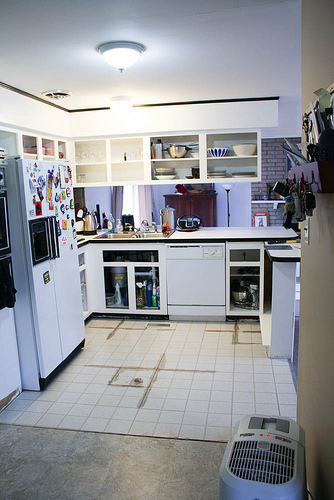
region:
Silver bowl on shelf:
[164, 141, 190, 161]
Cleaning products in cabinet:
[133, 274, 159, 308]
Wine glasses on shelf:
[73, 140, 107, 160]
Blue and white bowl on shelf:
[197, 138, 223, 155]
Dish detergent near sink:
[103, 212, 114, 231]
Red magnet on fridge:
[30, 198, 42, 215]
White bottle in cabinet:
[108, 278, 122, 306]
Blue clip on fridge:
[45, 164, 53, 178]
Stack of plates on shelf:
[151, 164, 176, 179]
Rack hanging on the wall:
[282, 104, 332, 196]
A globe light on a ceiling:
[95, 40, 144, 71]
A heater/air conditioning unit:
[218, 412, 310, 497]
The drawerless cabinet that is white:
[104, 264, 128, 308]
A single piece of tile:
[184, 397, 207, 411]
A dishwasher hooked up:
[165, 243, 224, 317]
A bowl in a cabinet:
[231, 142, 255, 154]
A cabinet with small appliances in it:
[148, 135, 201, 157]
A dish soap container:
[114, 283, 122, 303]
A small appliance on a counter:
[175, 212, 201, 230]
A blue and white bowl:
[207, 146, 228, 155]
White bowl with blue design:
[205, 142, 227, 160]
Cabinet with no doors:
[101, 244, 161, 307]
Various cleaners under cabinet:
[104, 265, 160, 311]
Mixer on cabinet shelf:
[229, 276, 260, 311]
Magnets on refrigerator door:
[22, 162, 73, 214]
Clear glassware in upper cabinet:
[74, 140, 105, 164]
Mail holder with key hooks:
[273, 84, 331, 228]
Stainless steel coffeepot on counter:
[79, 209, 98, 238]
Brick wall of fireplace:
[259, 137, 281, 189]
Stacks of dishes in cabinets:
[150, 164, 256, 182]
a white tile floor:
[1, 317, 300, 440]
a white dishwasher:
[167, 244, 228, 323]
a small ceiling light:
[98, 43, 145, 71]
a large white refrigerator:
[7, 155, 88, 393]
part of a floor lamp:
[219, 182, 237, 225]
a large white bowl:
[233, 140, 256, 156]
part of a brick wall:
[250, 139, 292, 226]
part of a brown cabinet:
[160, 192, 220, 225]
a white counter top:
[177, 223, 295, 236]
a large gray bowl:
[231, 287, 249, 302]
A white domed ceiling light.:
[95, 37, 144, 74]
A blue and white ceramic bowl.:
[206, 145, 230, 157]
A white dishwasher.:
[164, 237, 228, 322]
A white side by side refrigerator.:
[15, 156, 86, 389]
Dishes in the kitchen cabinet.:
[149, 134, 258, 180]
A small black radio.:
[175, 211, 201, 231]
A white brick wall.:
[263, 146, 285, 180]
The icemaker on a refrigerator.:
[28, 217, 50, 264]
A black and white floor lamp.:
[220, 182, 233, 225]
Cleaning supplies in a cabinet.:
[98, 246, 163, 312]